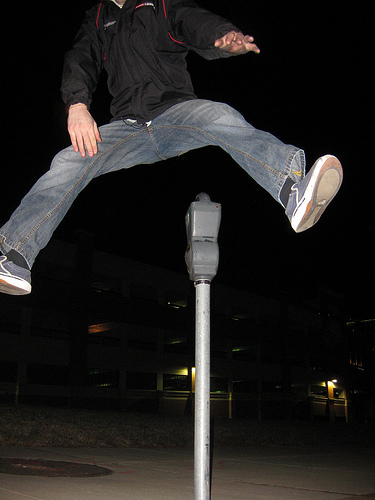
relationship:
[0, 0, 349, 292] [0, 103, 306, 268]
man wearing pants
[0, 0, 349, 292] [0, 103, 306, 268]
person wearing clothes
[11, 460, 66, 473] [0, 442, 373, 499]
graffiti on ground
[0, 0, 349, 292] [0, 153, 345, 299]
man wearing shoes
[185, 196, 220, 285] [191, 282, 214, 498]
meter on pole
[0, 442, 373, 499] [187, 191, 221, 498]
sidewalk behind meter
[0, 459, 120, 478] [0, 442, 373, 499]
manhole on sidewalk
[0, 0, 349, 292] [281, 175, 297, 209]
man wearing socks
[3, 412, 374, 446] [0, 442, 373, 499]
grass beyond sidewalk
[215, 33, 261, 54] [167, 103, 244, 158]
hand near thigh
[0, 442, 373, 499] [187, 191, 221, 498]
sidewalk around meter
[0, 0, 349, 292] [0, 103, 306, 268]
man wearing jeans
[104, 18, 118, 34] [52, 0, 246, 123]
lettering on jacket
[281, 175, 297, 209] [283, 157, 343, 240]
sock on foot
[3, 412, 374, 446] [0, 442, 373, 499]
grass along sidewalk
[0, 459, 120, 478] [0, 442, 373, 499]
manhole in sidewalk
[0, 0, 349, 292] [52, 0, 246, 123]
man wearing coat